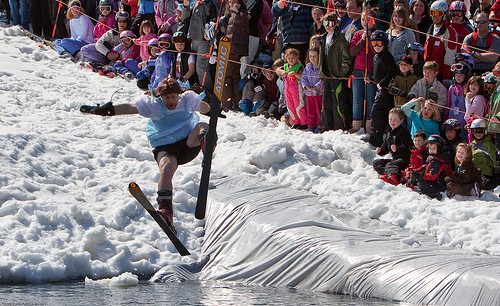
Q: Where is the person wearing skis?
A: In midair.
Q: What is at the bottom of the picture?
A: Body of water.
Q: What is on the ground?
A: White snow.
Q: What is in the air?
A: The man.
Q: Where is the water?
A: Below the man.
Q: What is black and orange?
A: Fence.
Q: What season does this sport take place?
A: Winter.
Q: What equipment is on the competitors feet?
A: Skis.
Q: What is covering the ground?
A: Snow.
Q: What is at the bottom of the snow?
A: Water.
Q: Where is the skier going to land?
A: Water.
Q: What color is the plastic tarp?
A: White.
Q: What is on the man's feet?
A: Skis.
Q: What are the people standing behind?
A: Rope.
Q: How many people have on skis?
A: 1.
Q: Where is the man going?
A: Into the water.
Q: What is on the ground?
A: Snow.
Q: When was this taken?
A: Winter.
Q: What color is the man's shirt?
A: Blue.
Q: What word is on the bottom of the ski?
A: Atomic.